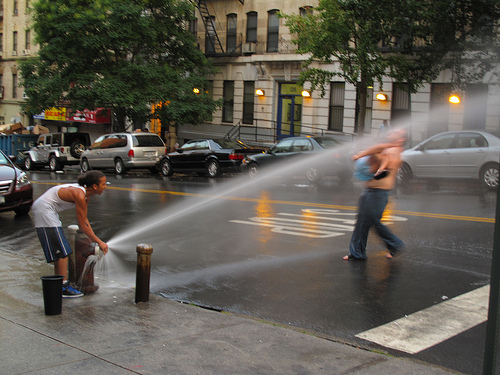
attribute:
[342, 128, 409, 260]
person — playing, shirtless, wet, shoeless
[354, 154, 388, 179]
person — playing, wet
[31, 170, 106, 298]
person — playing, turning, breaking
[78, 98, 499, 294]
water — white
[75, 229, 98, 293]
hydrant — open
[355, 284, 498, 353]
line — white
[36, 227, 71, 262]
shorts — blue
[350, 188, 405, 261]
pants — blue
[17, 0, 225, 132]
tree — large, green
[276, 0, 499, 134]
tree — green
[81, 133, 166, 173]
car — silver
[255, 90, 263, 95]
light — on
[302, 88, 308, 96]
light — on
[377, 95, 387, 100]
light — on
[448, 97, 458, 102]
light — on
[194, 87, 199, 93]
light — on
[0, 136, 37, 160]
dumpster — full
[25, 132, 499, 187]
cars — parked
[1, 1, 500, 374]
scene — daytime, downtown